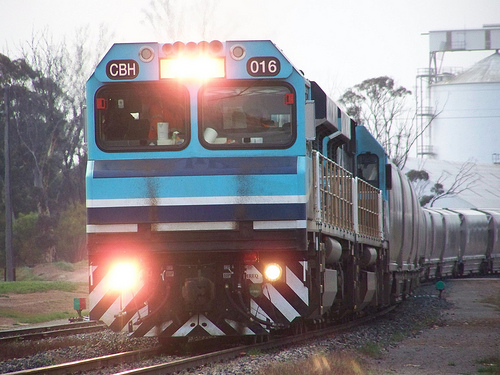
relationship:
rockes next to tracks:
[0, 279, 455, 374] [0, 318, 397, 374]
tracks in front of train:
[0, 318, 397, 374] [84, 39, 497, 339]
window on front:
[94, 84, 190, 152] [84, 41, 309, 339]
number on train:
[249, 57, 279, 74] [84, 39, 497, 339]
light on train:
[171, 49, 212, 84] [84, 39, 497, 339]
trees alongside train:
[3, 32, 86, 260] [84, 39, 497, 339]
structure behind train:
[398, 22, 498, 208] [84, 39, 497, 339]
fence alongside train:
[15, 235, 85, 273] [84, 39, 497, 339]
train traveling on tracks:
[84, 39, 497, 339] [0, 318, 397, 374]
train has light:
[84, 39, 497, 339] [261, 260, 283, 283]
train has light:
[84, 39, 497, 339] [171, 49, 212, 84]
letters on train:
[108, 63, 136, 76] [84, 39, 497, 339]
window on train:
[94, 82, 294, 149] [84, 39, 497, 339]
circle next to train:
[436, 280, 446, 290] [84, 39, 497, 339]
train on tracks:
[84, 39, 497, 339] [0, 318, 397, 374]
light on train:
[108, 258, 141, 292] [84, 39, 497, 339]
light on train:
[261, 260, 283, 283] [84, 39, 497, 339]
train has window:
[84, 39, 497, 339] [94, 82, 294, 149]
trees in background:
[3, 32, 86, 260] [3, 30, 89, 290]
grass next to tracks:
[0, 260, 88, 327] [0, 318, 397, 374]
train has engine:
[84, 39, 497, 339] [83, 35, 390, 338]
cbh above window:
[108, 63, 134, 75] [94, 84, 190, 152]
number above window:
[249, 57, 279, 74] [94, 82, 294, 149]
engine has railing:
[83, 35, 390, 338] [312, 150, 385, 245]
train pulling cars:
[84, 39, 497, 339] [390, 158, 500, 302]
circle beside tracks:
[436, 280, 446, 290] [0, 318, 397, 374]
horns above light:
[162, 40, 223, 55] [171, 49, 212, 84]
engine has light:
[83, 35, 390, 338] [108, 258, 141, 292]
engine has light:
[83, 35, 390, 338] [261, 260, 283, 283]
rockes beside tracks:
[0, 279, 455, 374] [0, 318, 397, 374]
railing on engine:
[312, 150, 385, 245] [83, 35, 390, 338]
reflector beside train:
[71, 298, 86, 312] [84, 39, 497, 339]